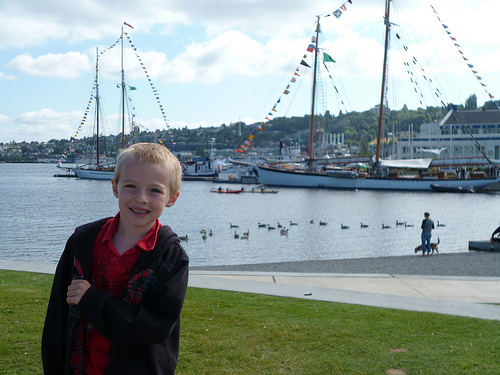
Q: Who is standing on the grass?
A: A boy.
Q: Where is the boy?
A: At a marina.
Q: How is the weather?
A: Blue skies with some clouds.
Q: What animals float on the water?
A: Ducks.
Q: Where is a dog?
A: At the shoreline with its owner.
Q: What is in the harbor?
A: Various water craft.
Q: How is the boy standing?
A: With a left arm holding his jacket.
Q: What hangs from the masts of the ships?
A: Decorative flags.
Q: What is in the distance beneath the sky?
A: Buildings and trees.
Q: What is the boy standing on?
A: Grass.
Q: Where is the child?
A: By the ocean.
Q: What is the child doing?
A: Standing for a photo.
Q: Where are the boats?
A: In the water.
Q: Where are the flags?
A: On the boats.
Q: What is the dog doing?
A: Smelling.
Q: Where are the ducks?
A: In the water.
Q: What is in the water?
A: Ducks.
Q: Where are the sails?
A: On the boats.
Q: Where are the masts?
A: On the boats.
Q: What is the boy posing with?
A: Large sailboats.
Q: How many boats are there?
A: Two.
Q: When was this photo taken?
A: During the day.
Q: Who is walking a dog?
A: A person in the background.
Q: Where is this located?
A: At a pier by the sea.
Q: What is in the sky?
A: Clouds.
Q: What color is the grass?
A: Green.